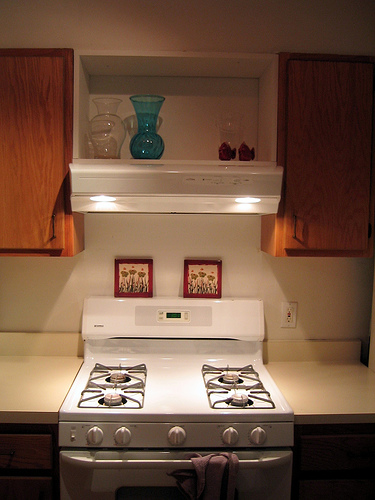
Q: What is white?
A: The stove.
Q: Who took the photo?
A: A photographer.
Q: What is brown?
A: The cabinets.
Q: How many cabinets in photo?
A: Two.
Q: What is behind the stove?
A: Pictures.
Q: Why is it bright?
A: The lighting in room.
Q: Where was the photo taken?
A: In the kitchen of a home.